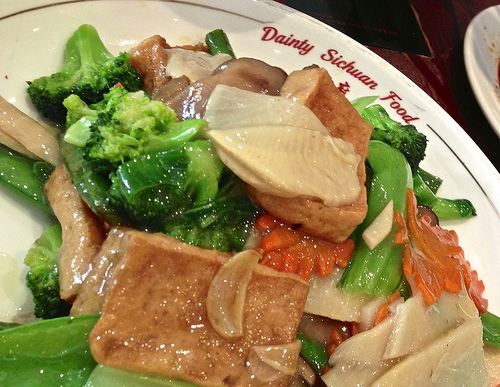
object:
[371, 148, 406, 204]
green bean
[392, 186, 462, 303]
carrot slice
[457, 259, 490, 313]
carrot slice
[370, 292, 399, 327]
carrot slice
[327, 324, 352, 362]
carrot slice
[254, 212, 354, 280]
carrot slice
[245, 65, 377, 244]
meat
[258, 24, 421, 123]
letters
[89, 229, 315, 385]
tofu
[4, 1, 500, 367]
dish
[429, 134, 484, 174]
ground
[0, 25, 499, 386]
food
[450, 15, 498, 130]
plate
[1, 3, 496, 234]
stripe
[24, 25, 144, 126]
broccoli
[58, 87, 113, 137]
green vegetable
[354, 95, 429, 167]
green vegetable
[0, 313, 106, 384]
green vegetable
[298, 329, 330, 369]
green vegetable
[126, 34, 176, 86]
meat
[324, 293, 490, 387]
meat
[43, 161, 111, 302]
meat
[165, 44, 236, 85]
meat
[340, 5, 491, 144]
table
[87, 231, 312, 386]
chunk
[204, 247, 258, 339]
garlic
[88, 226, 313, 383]
meat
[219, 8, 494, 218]
border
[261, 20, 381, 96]
dainty sichuan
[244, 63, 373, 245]
tofu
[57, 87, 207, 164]
broccoli